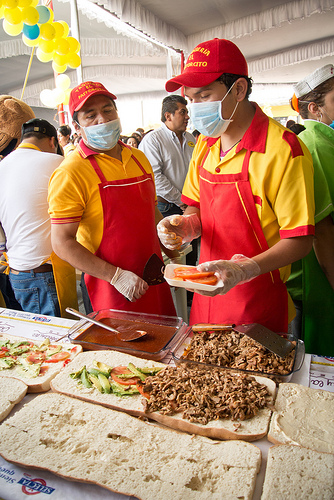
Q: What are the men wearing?
A: Red hats.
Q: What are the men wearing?
A: Yellow shirts.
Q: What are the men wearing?
A: Red aprons.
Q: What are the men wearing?
A: Latex gloves.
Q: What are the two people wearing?
A: White masks.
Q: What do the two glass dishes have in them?
A: Food.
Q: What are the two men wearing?
A: Red aprons.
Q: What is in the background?
A: Yellow and blue balloons.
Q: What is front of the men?
A: Several pieces of large bread.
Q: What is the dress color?
A: Yellow and red.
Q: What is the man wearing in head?
A: Cap.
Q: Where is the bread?
A: Table.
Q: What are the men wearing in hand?
A: Gloves.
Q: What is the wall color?
A: White.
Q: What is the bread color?
A: Brown.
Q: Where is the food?
A: Top of bread.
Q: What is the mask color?
A: Green.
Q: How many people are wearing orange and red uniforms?
A: Two.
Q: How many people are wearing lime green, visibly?
A: One.